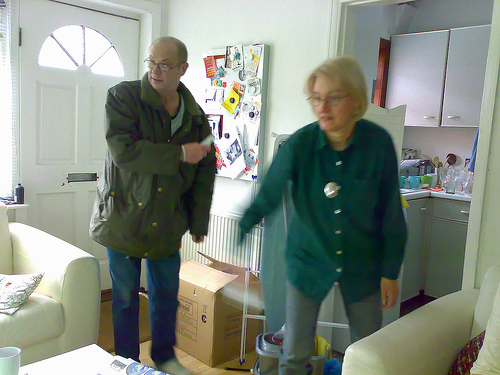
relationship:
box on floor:
[175, 247, 259, 365] [87, 289, 355, 374]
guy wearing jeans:
[88, 35, 218, 374] [104, 257, 179, 354]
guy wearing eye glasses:
[88, 35, 218, 374] [143, 56, 185, 72]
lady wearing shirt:
[235, 55, 409, 373] [234, 120, 407, 303]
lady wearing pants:
[235, 55, 409, 373] [278, 281, 384, 373]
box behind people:
[175, 250, 263, 367] [95, 40, 214, 363]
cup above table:
[1, 342, 24, 374] [1, 340, 168, 373]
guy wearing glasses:
[84, 33, 221, 374] [140, 54, 188, 74]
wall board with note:
[198, 40, 269, 191] [220, 87, 241, 112]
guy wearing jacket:
[88, 35, 218, 374] [90, 77, 216, 262]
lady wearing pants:
[235, 55, 409, 373] [298, 261, 428, 372]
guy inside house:
[88, 35, 218, 374] [4, 3, 491, 371]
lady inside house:
[235, 55, 409, 373] [4, 3, 491, 371]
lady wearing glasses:
[235, 55, 409, 373] [305, 93, 351, 106]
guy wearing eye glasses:
[88, 35, 218, 374] [143, 54, 181, 72]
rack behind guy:
[179, 203, 289, 317] [88, 35, 218, 374]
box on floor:
[175, 250, 263, 367] [77, 283, 382, 371]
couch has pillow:
[0, 210, 120, 359] [2, 259, 78, 343]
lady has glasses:
[223, 57, 427, 371] [425, 163, 460, 198]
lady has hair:
[235, 55, 409, 373] [294, 32, 385, 117]